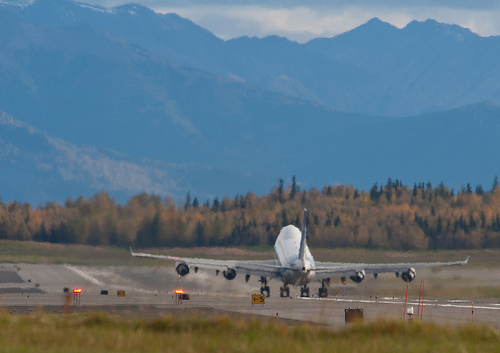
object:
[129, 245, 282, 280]
wing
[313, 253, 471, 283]
wing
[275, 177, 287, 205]
trees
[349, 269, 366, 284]
jet engine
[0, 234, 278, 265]
grass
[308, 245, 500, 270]
grass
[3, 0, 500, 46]
sky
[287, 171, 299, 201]
tree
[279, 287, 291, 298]
wheels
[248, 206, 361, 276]
tail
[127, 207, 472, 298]
airplane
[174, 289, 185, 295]
lights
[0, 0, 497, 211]
mountains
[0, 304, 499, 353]
grass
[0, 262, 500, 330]
runway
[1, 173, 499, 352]
forest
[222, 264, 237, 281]
jet engine